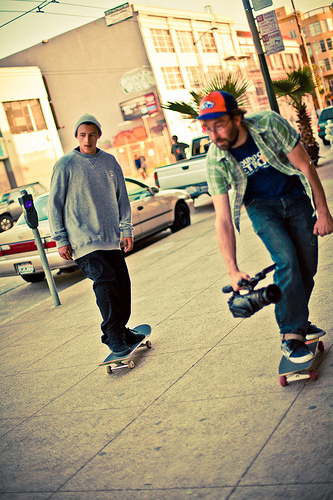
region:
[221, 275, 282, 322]
a black camera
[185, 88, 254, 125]
a red and blue cap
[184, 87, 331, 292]
man wears a squared shirt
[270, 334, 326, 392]
a black skateboard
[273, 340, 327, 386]
skateboard has red wheels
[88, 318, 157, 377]
skateboard has white wheels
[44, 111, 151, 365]
man wears a gray top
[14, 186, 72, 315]
a parking meter on sidewalk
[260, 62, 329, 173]
a palm on the sidewalk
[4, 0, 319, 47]
power lines above the people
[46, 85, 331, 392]
Two guys are on skateboards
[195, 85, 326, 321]
Man is holding a video camera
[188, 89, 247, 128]
An orange and blue hat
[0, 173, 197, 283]
A car is white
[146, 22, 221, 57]
Three windows on a building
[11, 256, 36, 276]
A white license plate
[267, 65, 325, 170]
A plam tree on the sidewalk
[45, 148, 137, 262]
A sweatshirt is gray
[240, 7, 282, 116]
A pole holding up a sign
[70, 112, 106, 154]
Hat on guy's head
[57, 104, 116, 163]
Man is wearing a beanie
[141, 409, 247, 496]
Sidewalk has a tile look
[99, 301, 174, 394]
Man standing on a skateboard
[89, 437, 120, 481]
Stain on the pavement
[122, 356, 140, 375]
Wheel on bottom of skateboard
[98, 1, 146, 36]
Sign on side of building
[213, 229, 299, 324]
Man holding a video camera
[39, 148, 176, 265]
Man wearing a sweatshirt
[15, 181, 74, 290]
Parking meter beside sidewalk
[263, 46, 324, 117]
Palm tree beside sidewalk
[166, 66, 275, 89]
green pointed palm leaves on tree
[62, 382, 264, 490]
large cement square on sidewalk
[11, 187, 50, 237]
silver parking meter on side of road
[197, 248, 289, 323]
black video camera in man's hands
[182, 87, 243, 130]
orange and blue hat on man's head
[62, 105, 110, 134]
grey stocking cap on guy's head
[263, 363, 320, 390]
red wheels on right skateboard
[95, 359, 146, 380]
orange wheels on left skateboard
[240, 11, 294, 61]
red and white street signs on pole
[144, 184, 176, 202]
side mirror on side of car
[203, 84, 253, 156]
the head of a man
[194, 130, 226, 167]
the nose of a man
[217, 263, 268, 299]
the hand of a man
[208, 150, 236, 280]
the arm of a man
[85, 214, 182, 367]
the legs of a man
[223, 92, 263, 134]
the ear of a man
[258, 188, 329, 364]
a man wearing pants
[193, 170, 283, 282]
a man wearing a shirt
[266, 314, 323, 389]
the feet of a man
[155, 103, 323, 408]
a man on a skatrboard